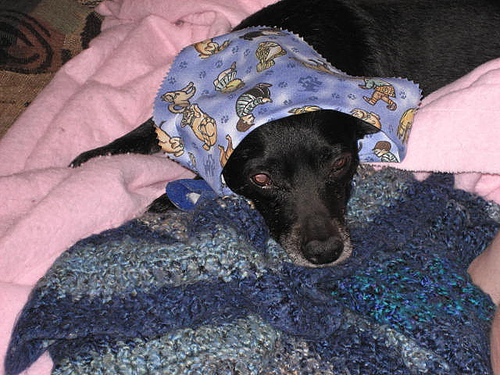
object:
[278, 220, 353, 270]
mouth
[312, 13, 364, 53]
hair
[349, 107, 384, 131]
character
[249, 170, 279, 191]
brown eyes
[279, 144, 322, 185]
fur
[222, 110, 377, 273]
face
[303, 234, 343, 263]
nose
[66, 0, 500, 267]
dog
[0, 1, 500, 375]
blanket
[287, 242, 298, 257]
white fur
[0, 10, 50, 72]
swirls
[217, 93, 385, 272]
head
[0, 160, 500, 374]
blue scarf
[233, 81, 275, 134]
animated character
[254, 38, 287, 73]
character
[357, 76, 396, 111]
character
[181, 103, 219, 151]
character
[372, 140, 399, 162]
character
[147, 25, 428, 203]
bib